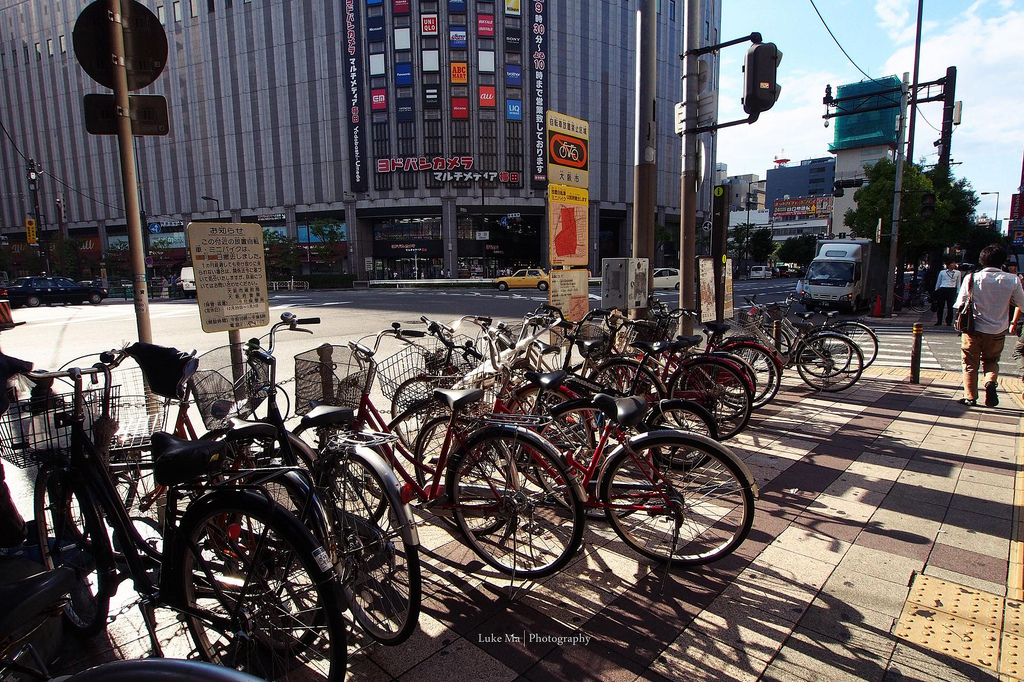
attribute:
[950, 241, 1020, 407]
pants — tan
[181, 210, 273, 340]
sign — white